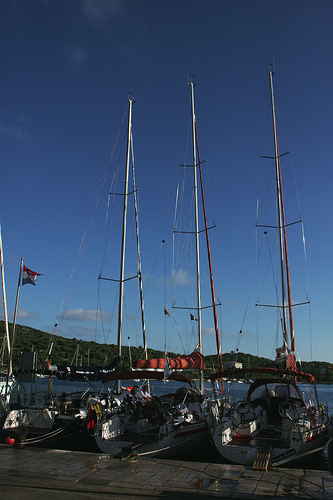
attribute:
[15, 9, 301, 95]
sky — blue, clear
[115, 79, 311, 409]
sails — tall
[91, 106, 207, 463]
boat — tied up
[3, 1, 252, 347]
clouds — white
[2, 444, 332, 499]
dock — wooden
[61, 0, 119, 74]
clouds — white, blue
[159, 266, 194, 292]
clouds — white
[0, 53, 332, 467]
boats — together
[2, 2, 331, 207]
sky — blue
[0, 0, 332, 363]
sky — blue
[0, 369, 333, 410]
water — calm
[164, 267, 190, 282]
cloud — white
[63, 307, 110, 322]
cloud — white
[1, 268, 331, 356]
clouds — white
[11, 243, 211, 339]
clouds — white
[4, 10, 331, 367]
area — large